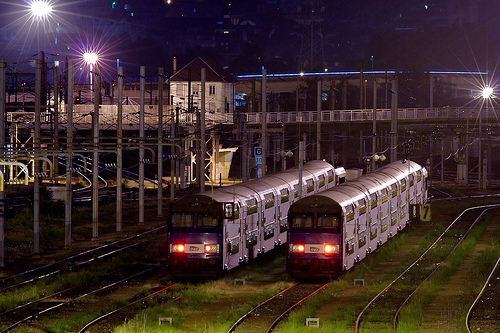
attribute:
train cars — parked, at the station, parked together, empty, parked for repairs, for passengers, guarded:
[160, 153, 432, 283]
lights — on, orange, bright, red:
[285, 240, 336, 257]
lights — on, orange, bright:
[171, 240, 220, 258]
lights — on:
[32, 3, 101, 67]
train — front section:
[284, 160, 433, 276]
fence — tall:
[8, 63, 496, 264]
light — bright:
[81, 51, 103, 72]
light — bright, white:
[29, 4, 56, 16]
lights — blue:
[233, 70, 499, 80]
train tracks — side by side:
[1, 183, 497, 330]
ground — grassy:
[4, 176, 497, 332]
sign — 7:
[416, 202, 433, 225]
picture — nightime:
[0, 2, 499, 329]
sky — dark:
[5, 0, 495, 90]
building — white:
[168, 54, 234, 128]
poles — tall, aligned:
[27, 53, 171, 260]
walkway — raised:
[16, 101, 500, 125]